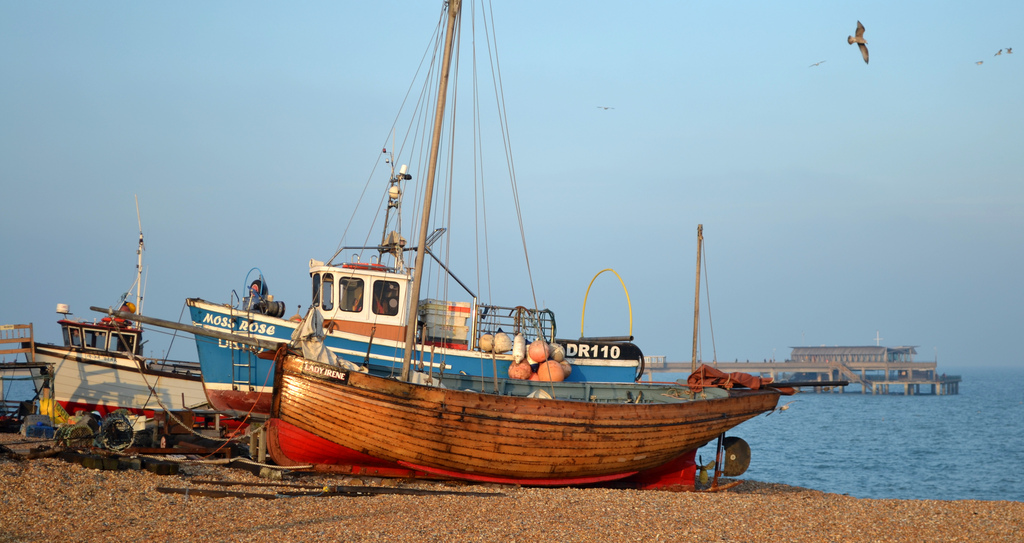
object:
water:
[5, 366, 1023, 503]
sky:
[0, 4, 1022, 365]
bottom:
[266, 414, 699, 500]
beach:
[0, 415, 1024, 536]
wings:
[862, 20, 873, 72]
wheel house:
[52, 307, 146, 360]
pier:
[659, 332, 981, 402]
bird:
[848, 21, 872, 64]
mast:
[392, 2, 468, 337]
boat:
[187, 261, 783, 487]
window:
[374, 281, 400, 316]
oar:
[378, 345, 502, 382]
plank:
[142, 463, 367, 511]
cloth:
[665, 351, 836, 431]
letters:
[565, 343, 620, 359]